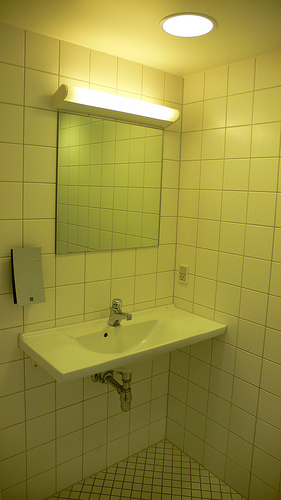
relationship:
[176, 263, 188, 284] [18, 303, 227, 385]
outlet near sink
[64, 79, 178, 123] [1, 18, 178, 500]
beam attached to walls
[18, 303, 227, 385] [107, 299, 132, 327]
sink has a faucet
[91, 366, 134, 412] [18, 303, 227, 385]
pipes are under sink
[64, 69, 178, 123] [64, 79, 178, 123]
beam coming from a beam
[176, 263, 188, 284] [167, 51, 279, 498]
outlet attached to wall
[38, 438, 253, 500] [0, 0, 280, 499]
tiles are in restroom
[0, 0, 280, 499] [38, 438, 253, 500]
restroom has tiles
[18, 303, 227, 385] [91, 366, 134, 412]
sink has drainage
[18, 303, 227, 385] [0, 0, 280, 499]
sink in restroom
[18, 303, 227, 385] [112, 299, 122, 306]
sink has a tap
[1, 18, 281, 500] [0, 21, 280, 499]
walls have tiles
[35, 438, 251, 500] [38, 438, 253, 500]
floor has tiles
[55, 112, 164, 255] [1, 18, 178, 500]
mirror on walls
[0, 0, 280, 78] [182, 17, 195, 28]
ceiling has a light bulb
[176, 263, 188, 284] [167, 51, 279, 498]
outlet on wall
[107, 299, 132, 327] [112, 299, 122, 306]
faucet has a tap